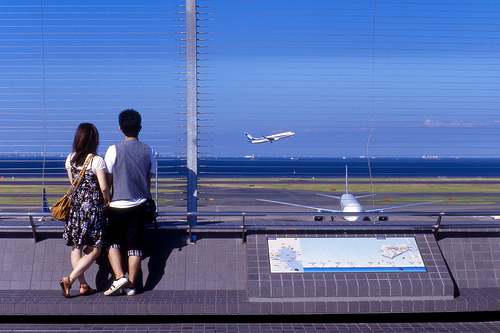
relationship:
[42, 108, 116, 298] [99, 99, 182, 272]
woman with man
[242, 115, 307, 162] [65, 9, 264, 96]
plane in sky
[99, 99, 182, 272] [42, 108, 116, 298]
man with woman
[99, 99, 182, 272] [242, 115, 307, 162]
man watching plane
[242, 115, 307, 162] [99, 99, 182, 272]
plane near man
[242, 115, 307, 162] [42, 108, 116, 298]
plane near woman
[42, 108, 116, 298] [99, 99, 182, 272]
woman and man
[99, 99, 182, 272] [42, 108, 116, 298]
man and woman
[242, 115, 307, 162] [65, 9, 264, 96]
plane above sky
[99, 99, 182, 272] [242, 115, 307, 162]
man close to plane